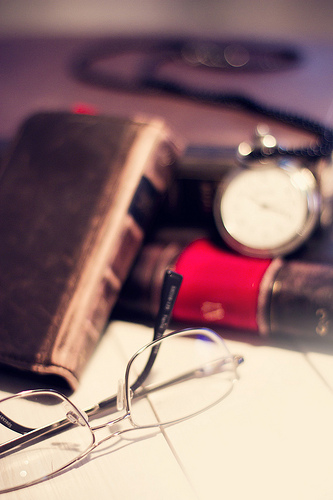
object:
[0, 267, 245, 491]
glasses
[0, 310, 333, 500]
table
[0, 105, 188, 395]
book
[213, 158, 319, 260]
watch